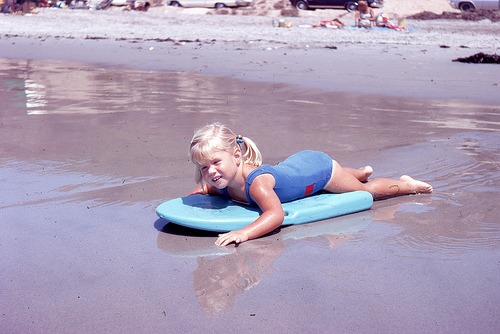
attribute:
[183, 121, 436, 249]
girl — blonde, little, young, laying down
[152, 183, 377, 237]
boogie board — light, small, blue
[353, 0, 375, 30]
person — sitting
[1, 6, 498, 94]
beach — rocky, sandy, wet, brown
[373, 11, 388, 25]
ball — colorful, colored, red blue, white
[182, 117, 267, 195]
hair — blonde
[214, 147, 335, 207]
bathing suit — blue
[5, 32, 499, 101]
sand — wet, grey, smooth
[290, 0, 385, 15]
car — grey, black, parked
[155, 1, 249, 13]
car — parked, white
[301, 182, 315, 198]
decoration — red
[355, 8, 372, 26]
beach dress — blue, white